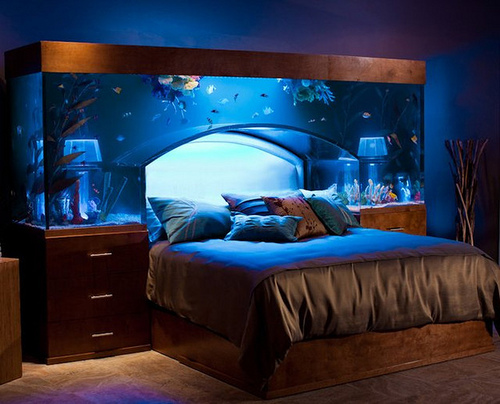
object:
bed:
[141, 223, 499, 401]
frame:
[143, 294, 496, 402]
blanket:
[146, 226, 500, 394]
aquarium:
[0, 37, 428, 235]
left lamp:
[58, 133, 105, 226]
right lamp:
[355, 135, 391, 206]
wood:
[1, 38, 429, 87]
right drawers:
[359, 208, 429, 238]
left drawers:
[46, 307, 153, 359]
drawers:
[43, 231, 151, 280]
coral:
[361, 177, 387, 205]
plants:
[23, 100, 44, 223]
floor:
[0, 348, 268, 404]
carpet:
[309, 390, 481, 401]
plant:
[438, 134, 497, 247]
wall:
[0, 0, 500, 239]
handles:
[86, 249, 115, 260]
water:
[50, 83, 131, 145]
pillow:
[224, 211, 305, 244]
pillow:
[258, 194, 330, 243]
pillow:
[145, 195, 234, 247]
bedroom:
[0, 0, 500, 404]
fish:
[382, 185, 400, 202]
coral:
[272, 77, 338, 106]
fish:
[361, 108, 377, 124]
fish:
[150, 112, 162, 123]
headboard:
[139, 130, 309, 212]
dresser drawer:
[44, 270, 151, 323]